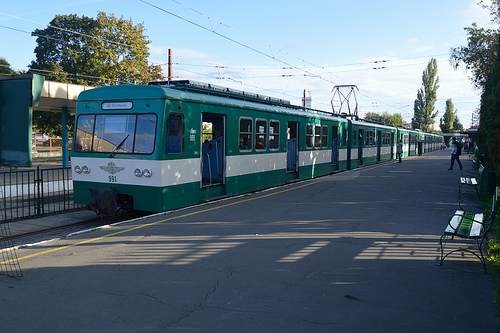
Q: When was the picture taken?
A: During the daytime.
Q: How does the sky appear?
A: Blue with clouds.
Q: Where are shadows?
A: On the ground.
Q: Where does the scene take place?
A: At a train station.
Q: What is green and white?
A: The train.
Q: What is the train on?
A: Train tracks.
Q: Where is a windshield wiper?
A: On train's front window.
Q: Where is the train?
A: On the tracks.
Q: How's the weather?
A: Sunny.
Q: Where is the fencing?
A: Behind the train.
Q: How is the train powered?
A: Electricity.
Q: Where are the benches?
A: At the side of the walkway.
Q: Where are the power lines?
A: Above the train.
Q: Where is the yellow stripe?
A: On the walkway.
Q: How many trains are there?
A: One.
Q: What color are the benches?
A: Green and white.